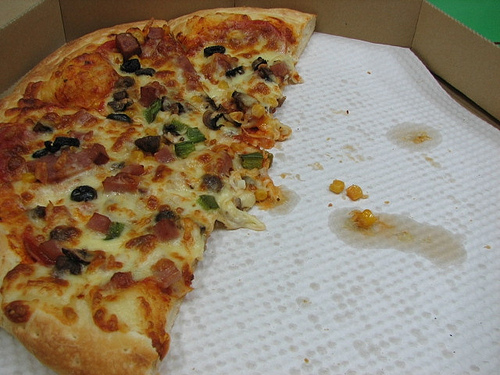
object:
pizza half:
[6, 5, 316, 374]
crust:
[26, 322, 156, 372]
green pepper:
[195, 192, 220, 214]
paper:
[158, 29, 498, 374]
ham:
[108, 34, 155, 64]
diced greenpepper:
[242, 155, 263, 166]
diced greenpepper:
[169, 137, 196, 156]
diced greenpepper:
[187, 120, 204, 144]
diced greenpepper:
[106, 215, 125, 240]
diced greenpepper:
[141, 105, 161, 120]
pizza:
[0, 0, 316, 374]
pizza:
[10, 38, 219, 355]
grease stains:
[332, 172, 432, 307]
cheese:
[90, 227, 120, 255]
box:
[1, 0, 498, 372]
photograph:
[1, 5, 496, 367]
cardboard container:
[3, 4, 487, 362]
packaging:
[3, 0, 498, 372]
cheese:
[207, 199, 268, 234]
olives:
[31, 133, 86, 165]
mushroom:
[56, 245, 96, 273]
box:
[412, 19, 497, 119]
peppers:
[154, 108, 275, 217]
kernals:
[98, 49, 221, 158]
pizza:
[327, 110, 483, 290]